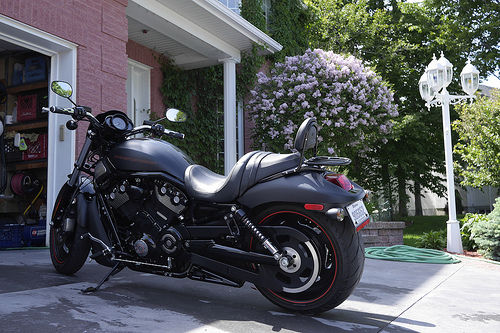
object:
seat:
[185, 146, 298, 203]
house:
[0, 0, 288, 255]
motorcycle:
[41, 77, 370, 316]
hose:
[357, 244, 465, 267]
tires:
[240, 203, 370, 317]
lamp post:
[435, 100, 466, 256]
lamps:
[456, 52, 478, 102]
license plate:
[341, 199, 374, 232]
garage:
[0, 26, 77, 253]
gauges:
[105, 112, 135, 132]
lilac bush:
[248, 47, 402, 189]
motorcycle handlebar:
[133, 122, 189, 140]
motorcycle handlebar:
[40, 104, 97, 121]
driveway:
[0, 242, 500, 332]